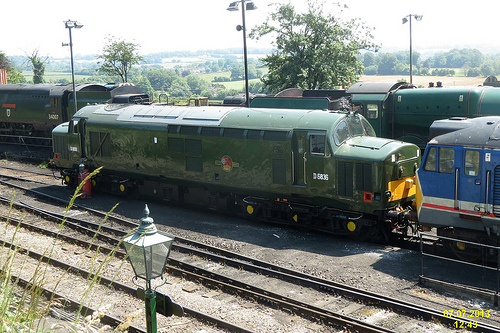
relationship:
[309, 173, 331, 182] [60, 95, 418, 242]
numbers on train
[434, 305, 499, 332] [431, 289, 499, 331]
time stamp in corner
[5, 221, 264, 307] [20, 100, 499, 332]
tracks for railroad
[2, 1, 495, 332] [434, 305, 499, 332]
picture has time stamp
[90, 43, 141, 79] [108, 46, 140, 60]
tree has leaves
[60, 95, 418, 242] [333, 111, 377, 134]
train has windshield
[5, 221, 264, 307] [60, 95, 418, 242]
tracks next to train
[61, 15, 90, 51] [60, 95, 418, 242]
light above train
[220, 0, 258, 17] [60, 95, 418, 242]
light above train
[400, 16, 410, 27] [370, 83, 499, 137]
lamp above train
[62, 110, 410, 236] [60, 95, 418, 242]
car of train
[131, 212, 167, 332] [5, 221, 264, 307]
street lamp at track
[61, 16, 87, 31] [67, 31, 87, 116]
lamp on pole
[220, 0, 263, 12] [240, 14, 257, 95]
lamp on pole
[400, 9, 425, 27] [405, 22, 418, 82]
lamp on pole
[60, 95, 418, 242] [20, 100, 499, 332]
train in train yard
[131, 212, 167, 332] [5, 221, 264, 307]
street lamp near tracks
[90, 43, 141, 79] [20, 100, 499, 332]
tree near train yard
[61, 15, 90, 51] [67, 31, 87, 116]
light on pole